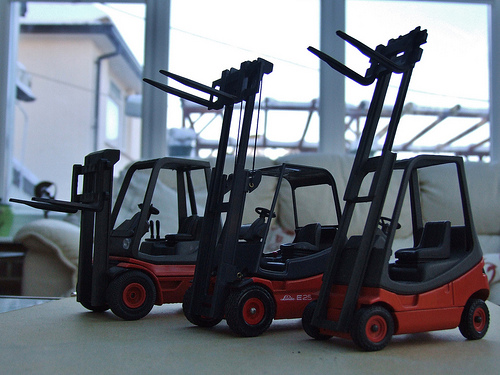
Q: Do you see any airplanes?
A: No, there are no airplanes.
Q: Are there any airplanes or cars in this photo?
A: No, there are no airplanes or cars.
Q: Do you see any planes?
A: No, there are no planes.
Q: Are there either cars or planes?
A: No, there are no planes or cars.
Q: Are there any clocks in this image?
A: No, there are no clocks.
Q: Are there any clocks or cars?
A: No, there are no clocks or cars.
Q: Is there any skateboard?
A: No, there are no skateboards.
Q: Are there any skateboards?
A: No, there are no skateboards.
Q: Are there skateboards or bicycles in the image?
A: No, there are no skateboards or bicycles.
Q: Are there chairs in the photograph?
A: Yes, there is a chair.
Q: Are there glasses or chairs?
A: Yes, there is a chair.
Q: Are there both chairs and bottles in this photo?
A: No, there is a chair but no bottles.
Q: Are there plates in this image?
A: No, there are no plates.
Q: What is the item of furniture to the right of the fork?
A: The piece of furniture is a chair.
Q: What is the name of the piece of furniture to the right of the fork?
A: The piece of furniture is a chair.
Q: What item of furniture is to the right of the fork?
A: The piece of furniture is a chair.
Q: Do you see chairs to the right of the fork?
A: Yes, there is a chair to the right of the fork.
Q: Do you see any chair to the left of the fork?
A: No, the chair is to the right of the fork.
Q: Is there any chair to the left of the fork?
A: No, the chair is to the right of the fork.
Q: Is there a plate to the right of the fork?
A: No, there is a chair to the right of the fork.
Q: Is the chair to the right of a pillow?
A: No, the chair is to the right of a fork.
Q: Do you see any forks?
A: Yes, there is a fork.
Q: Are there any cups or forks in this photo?
A: Yes, there is a fork.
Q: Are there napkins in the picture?
A: No, there are no napkins.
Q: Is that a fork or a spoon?
A: That is a fork.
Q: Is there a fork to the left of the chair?
A: Yes, there is a fork to the left of the chair.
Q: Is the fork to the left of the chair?
A: Yes, the fork is to the left of the chair.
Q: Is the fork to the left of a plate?
A: No, the fork is to the left of the chair.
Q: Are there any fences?
A: No, there are no fences.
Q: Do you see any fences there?
A: No, there are no fences.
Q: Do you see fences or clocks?
A: No, there are no fences or clocks.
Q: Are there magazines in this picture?
A: No, there are no magazines.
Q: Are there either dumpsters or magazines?
A: No, there are no magazines or dumpsters.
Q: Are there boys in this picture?
A: No, there are no boys.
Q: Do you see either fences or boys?
A: No, there are no boys or fences.